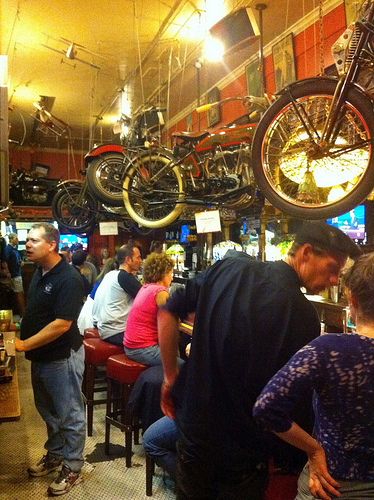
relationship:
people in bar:
[56, 221, 328, 381] [0, 0, 372, 498]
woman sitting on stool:
[121, 251, 185, 367] [98, 336, 162, 483]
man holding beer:
[11, 221, 87, 499] [16, 256, 26, 267]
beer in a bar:
[16, 256, 26, 267] [0, 0, 372, 498]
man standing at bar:
[11, 221, 87, 499] [1, 308, 27, 422]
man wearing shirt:
[94, 235, 151, 345] [89, 258, 131, 339]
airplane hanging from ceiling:
[38, 20, 128, 87] [1, 2, 341, 145]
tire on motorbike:
[220, 59, 373, 221] [251, 0, 373, 220]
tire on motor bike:
[158, 207, 178, 223] [131, 117, 264, 214]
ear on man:
[291, 238, 316, 260] [138, 198, 358, 498]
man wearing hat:
[155, 220, 366, 499] [294, 221, 362, 260]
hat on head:
[294, 221, 362, 260] [288, 221, 347, 292]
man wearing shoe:
[11, 221, 87, 499] [48, 463, 80, 494]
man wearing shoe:
[11, 221, 87, 499] [28, 449, 64, 481]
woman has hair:
[121, 251, 185, 367] [142, 251, 179, 288]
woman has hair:
[157, 221, 374, 499] [341, 251, 373, 324]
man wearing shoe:
[11, 221, 87, 499] [44, 463, 91, 498]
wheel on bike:
[275, 74, 365, 213] [272, 28, 364, 220]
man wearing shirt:
[11, 221, 87, 499] [11, 260, 84, 364]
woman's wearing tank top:
[39, 205, 260, 318] [123, 282, 166, 350]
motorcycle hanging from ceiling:
[126, 84, 294, 226] [1, 2, 341, 145]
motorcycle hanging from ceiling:
[249, 0, 370, 220] [1, 2, 341, 145]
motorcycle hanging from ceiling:
[50, 165, 156, 236] [1, 2, 341, 145]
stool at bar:
[81, 337, 124, 436] [0, 0, 372, 498]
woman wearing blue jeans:
[120, 254, 185, 373] [121, 337, 186, 368]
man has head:
[11, 221, 87, 499] [22, 224, 62, 261]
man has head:
[202, 222, 330, 451] [289, 223, 356, 294]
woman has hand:
[255, 250, 362, 496] [300, 450, 340, 495]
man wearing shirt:
[155, 220, 366, 499] [158, 250, 319, 443]